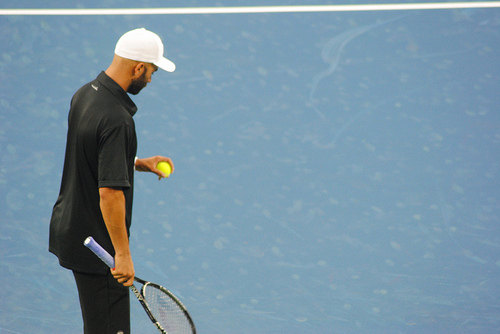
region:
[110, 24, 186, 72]
the hat is white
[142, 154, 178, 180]
the ball is yellow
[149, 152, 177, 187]
the ball is round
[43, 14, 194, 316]
the man is holding a racket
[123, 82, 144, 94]
the beard is black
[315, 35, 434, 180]
background is blue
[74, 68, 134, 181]
the shirt is black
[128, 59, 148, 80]
the man has an ear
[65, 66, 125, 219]
the man wears a shirt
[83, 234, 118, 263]
the handle is light blue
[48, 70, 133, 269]
black cotton polo shirt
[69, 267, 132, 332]
black cotton tennis shorts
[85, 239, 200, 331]
blue and black tennis racquet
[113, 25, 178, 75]
white baseball cap on head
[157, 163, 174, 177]
yellow tennis ball in hand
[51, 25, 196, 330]
man playing tennis game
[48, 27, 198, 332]
man holding tennis ball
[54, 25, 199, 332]
man holding tennis racquet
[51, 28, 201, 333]
man wearing black shirt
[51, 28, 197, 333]
man wearing white hat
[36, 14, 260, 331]
this is a player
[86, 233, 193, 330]
this is a racket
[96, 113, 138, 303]
arm of a man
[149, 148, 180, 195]
this is a ball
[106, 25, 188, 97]
the man has a white cap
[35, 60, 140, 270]
the man is wearing a black shirt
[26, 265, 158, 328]
the man is in black pants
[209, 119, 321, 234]
the background is blue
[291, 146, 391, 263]
the background is blue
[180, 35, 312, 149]
the background is blue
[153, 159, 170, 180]
A yellow tennis ball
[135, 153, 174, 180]
Hand holding tennis ball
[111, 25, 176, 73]
White baseball cap on man's head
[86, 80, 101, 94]
Nike corporate logo emblem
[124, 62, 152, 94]
Man with bearded face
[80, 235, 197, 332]
Purple handled tennis racket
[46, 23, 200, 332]
Man preparing to serve tennis ball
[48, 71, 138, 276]
A black tennis shirt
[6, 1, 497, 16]
Tennis court boundary line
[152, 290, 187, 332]
Corporate logo on tennis racket webbing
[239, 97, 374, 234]
blue ground under the man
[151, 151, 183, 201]
green ball in man's hand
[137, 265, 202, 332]
racket in man's hand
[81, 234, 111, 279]
handle of the racket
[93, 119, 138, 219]
sleeve of the shirt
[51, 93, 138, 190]
shirt on the man's back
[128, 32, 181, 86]
white hat on the man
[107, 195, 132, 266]
arm of the man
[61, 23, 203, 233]
man looking at the ground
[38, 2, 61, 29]
white line on the ground